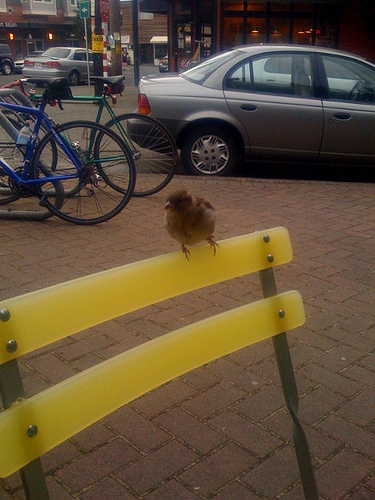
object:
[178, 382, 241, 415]
brick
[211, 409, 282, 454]
brick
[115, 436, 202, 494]
brick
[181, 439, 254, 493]
brick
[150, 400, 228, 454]
brick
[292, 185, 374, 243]
sidewalk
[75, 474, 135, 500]
brick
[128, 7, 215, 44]
background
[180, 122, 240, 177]
back tire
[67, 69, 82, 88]
back tire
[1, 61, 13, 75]
back tire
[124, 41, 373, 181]
car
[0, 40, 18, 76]
car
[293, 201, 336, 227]
brick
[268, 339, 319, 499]
black iron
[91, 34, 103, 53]
sign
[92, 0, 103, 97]
pole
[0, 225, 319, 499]
bench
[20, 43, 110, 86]
car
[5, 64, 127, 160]
street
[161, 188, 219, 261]
bird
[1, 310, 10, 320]
screw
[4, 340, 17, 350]
screw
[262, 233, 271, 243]
screw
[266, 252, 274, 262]
screw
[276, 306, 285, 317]
screw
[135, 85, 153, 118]
tail light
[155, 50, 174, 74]
car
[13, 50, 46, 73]
car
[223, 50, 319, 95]
window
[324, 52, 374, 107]
window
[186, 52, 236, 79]
window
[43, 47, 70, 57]
window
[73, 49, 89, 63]
window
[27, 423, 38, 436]
bolt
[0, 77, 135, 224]
bicycle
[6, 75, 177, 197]
bicycle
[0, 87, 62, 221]
bike rack